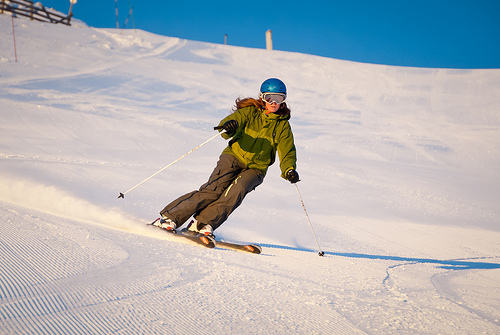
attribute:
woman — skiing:
[155, 78, 299, 236]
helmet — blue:
[259, 76, 286, 96]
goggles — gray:
[261, 92, 287, 103]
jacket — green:
[217, 105, 299, 174]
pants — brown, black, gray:
[158, 152, 267, 230]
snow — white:
[2, 14, 500, 334]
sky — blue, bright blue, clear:
[36, 0, 499, 69]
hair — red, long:
[233, 96, 265, 109]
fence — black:
[0, 0, 76, 27]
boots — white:
[155, 214, 219, 238]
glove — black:
[222, 119, 238, 133]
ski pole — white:
[116, 128, 227, 201]